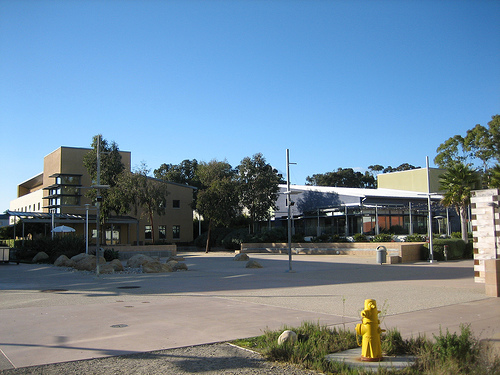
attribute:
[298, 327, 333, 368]
grass — green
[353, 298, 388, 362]
fire hydrant — yellow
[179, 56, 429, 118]
sky — clear, blue